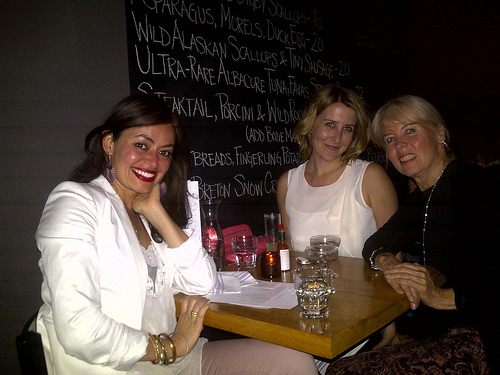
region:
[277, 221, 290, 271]
Tabasco sauce in a small bottle with a red cap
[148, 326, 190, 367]
A bunch of bangle bracelets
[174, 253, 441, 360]
A wood table top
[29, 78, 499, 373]
Three woman sitting at a table in a restaurant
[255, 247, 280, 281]
A small red frosted glass candle holder with a flame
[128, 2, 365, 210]
Blackboard with a menu written with white chalk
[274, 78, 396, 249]
Smiling blonde wearing a sleeveless silk top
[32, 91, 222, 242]
Pretty dark haired woman wearing red lipstick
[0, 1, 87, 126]
Section of a gray wall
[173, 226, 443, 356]
A table with some glasses and other item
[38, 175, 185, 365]
the blazer is white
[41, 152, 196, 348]
the blazer is whitethe blazer is white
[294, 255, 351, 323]
glasses on the table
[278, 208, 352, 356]
glasses on the table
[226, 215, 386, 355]
glasses on the table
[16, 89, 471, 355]
a group at a table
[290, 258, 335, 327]
a glass on the table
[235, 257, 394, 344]
a brown wooden table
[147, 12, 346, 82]
a menu broad on the wall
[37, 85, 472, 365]
three woman sitting at a table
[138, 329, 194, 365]
gold bracelets on wrist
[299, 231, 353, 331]
three glasses on a table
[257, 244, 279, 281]
a lite candle on a table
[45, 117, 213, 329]
a woman dressed in white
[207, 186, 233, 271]
a tall holder of water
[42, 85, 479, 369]
three women at table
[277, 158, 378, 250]
plain white sleeveless top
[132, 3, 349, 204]
white chalk on black board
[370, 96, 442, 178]
blonde hair on woman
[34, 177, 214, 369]
white jacket on woman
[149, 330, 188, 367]
metal braclets on wrist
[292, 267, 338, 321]
clear glass on table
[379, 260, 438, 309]
hand on top of another hand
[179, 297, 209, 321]
fingers with one ring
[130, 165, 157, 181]
white teeth in red lips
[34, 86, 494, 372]
Three woman sitting down at a table.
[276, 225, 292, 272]
A bottle of Tabasco sauce.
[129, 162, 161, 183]
Lips with red lipstick on them.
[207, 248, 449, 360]
a wooden small table.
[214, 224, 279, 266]
A pink wallet.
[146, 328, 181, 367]
Gold bracelets.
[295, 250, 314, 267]
A white cellphone.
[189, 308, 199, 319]
Gold rings.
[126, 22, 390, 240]
A large chalkboard.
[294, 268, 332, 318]
A clear small glass.